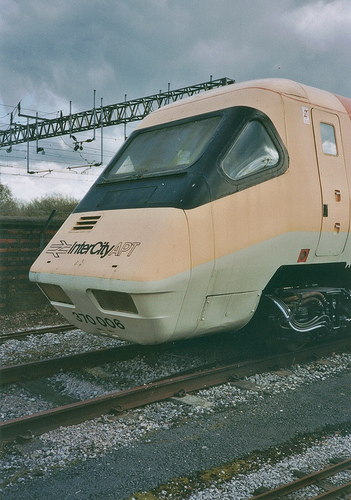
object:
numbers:
[113, 319, 125, 330]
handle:
[335, 224, 341, 229]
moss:
[126, 447, 270, 500]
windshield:
[221, 119, 279, 180]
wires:
[76, 133, 124, 141]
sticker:
[302, 106, 310, 125]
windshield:
[105, 117, 221, 178]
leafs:
[39, 190, 80, 207]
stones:
[6, 340, 23, 348]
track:
[255, 454, 349, 498]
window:
[104, 115, 222, 178]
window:
[221, 120, 278, 179]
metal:
[48, 322, 199, 432]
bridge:
[0, 75, 235, 173]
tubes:
[282, 292, 326, 309]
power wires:
[0, 104, 60, 116]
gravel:
[65, 397, 218, 448]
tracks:
[0, 337, 351, 446]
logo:
[46, 240, 141, 259]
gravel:
[56, 358, 160, 397]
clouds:
[0, 0, 351, 207]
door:
[310, 107, 349, 257]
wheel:
[270, 297, 309, 352]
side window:
[320, 122, 337, 155]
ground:
[0, 334, 347, 497]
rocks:
[217, 476, 274, 491]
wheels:
[312, 288, 350, 343]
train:
[28, 78, 351, 353]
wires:
[0, 172, 93, 183]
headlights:
[39, 283, 73, 305]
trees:
[1, 179, 87, 217]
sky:
[1, 3, 349, 204]